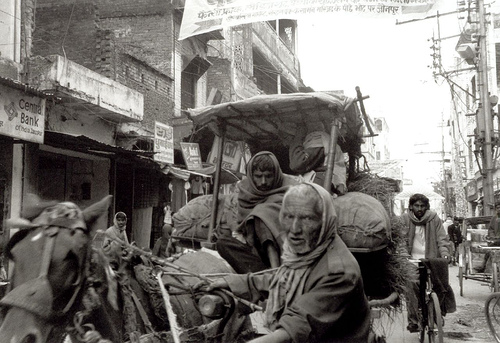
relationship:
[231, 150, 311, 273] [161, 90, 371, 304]
man seated on cart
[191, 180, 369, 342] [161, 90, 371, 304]
man seated on cart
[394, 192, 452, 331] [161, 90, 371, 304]
man seated on cart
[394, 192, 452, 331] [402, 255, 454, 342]
man riding bicycle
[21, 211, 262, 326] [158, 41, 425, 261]
horse pilling cart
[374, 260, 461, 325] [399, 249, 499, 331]
bicycle moving through street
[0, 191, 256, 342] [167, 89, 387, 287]
horse pushing cart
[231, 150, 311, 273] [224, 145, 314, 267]
man wrapped in blanket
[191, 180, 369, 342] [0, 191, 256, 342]
man holding horse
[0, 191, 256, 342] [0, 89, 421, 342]
horse pulling cart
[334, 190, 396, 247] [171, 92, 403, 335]
sacks on cart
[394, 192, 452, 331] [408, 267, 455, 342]
man riding bicycle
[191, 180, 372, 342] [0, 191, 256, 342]
man leading horse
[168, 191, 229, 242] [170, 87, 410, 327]
bag on wagon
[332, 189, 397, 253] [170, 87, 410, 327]
sacks on wagon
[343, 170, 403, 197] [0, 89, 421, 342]
straw on cart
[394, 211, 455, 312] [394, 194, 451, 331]
coat on man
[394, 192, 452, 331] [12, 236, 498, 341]
man on street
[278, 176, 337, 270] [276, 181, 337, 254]
robe on head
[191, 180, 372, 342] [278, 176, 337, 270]
man wears robe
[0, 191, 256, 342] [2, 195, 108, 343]
horse has gold helmet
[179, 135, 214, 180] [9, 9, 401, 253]
sign on building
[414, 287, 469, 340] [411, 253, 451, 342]
wheel on bicycle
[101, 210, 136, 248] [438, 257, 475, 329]
man standing and watching along road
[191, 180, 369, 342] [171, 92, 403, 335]
man pushing cart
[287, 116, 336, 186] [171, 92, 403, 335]
person sitting on cart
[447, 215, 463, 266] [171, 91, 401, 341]
man riding on wagon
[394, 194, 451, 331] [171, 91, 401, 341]
man riding on wagon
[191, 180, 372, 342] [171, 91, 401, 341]
man riding on wagon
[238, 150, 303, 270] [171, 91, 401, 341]
man riding on wagon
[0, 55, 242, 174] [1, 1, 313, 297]
signs on building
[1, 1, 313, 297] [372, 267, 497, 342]
building along street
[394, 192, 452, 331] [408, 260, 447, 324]
man wearing pants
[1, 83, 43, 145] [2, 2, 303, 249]
sign on building